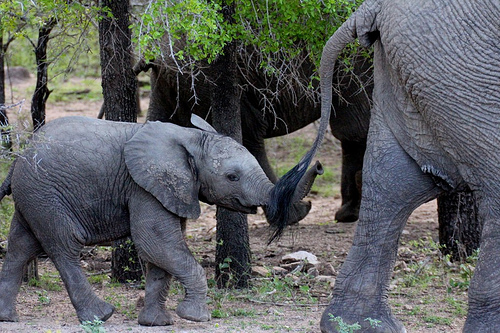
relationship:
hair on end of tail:
[258, 147, 332, 247] [252, 15, 364, 225]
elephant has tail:
[288, 0, 497, 332] [265, 3, 380, 257]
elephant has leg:
[288, 0, 497, 332] [320, 129, 430, 329]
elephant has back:
[0, 110, 321, 332] [22, 121, 149, 174]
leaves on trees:
[170, 14, 327, 69] [44, 12, 269, 258]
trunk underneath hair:
[263, 159, 320, 209] [272, 154, 304, 229]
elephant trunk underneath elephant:
[245, 150, 341, 223] [0, 110, 321, 332]